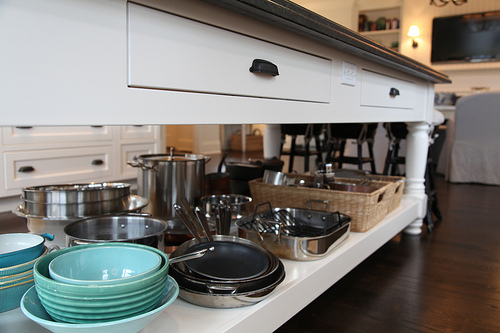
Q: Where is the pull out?
A: The drawer.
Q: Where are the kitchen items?
A: On shelf.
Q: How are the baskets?
A: Side by side.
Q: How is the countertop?
A: Granite.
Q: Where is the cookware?
A: On shelf.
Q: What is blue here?
A: Bowls.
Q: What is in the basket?
A: Misc. items.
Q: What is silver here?
A: Pots.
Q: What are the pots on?
A: Shelf.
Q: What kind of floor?
A: Hard wood.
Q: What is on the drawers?
A: Knobs.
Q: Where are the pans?
A: On the shelf.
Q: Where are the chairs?
A: In the back.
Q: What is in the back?
A: Chairs.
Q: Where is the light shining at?
A: On wall.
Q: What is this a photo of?
A: The kitchen.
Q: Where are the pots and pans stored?
A: On the shelf.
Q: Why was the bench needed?
A: To store pots and pans.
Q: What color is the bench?
A: White.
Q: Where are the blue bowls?
A: Bottom shelf.